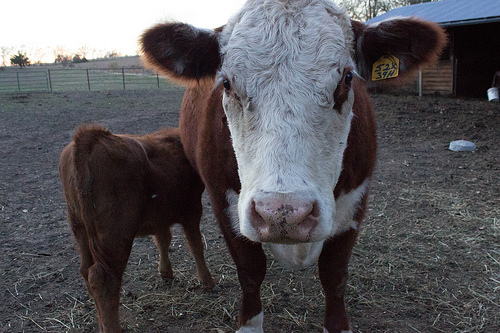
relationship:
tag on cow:
[371, 59, 400, 78] [135, 0, 450, 327]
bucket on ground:
[483, 87, 499, 106] [3, 89, 499, 332]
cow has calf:
[135, 0, 450, 327] [65, 116, 216, 332]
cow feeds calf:
[135, 0, 450, 327] [65, 116, 216, 332]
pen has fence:
[5, 91, 499, 332] [3, 65, 185, 93]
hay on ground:
[2, 90, 499, 332] [3, 89, 499, 332]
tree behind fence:
[13, 53, 27, 67] [3, 65, 185, 93]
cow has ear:
[135, 0, 450, 327] [361, 18, 444, 79]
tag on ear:
[371, 59, 400, 78] [361, 18, 444, 79]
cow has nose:
[135, 0, 450, 327] [248, 188, 323, 240]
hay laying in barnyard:
[0, 91, 500, 332] [0, 0, 500, 333]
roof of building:
[336, 9, 498, 43] [373, 0, 493, 95]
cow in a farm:
[135, 0, 450, 327] [2, 1, 494, 329]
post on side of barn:
[414, 70, 426, 97] [361, 0, 496, 101]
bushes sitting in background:
[56, 52, 66, 64] [2, 3, 246, 70]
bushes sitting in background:
[61, 56, 73, 64] [2, 3, 246, 70]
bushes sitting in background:
[70, 53, 81, 65] [2, 3, 246, 70]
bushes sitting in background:
[81, 55, 89, 62] [2, 3, 246, 70]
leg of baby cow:
[180, 207, 222, 289] [58, 121, 225, 332]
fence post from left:
[83, 67, 90, 88] [0, 3, 12, 327]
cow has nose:
[135, 0, 450, 327] [242, 191, 331, 245]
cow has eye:
[135, 0, 450, 327] [330, 58, 362, 99]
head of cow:
[139, 5, 449, 246] [135, 0, 450, 327]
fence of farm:
[0, 67, 174, 90] [2, 1, 494, 329]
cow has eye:
[135, 0, 450, 327] [216, 76, 235, 99]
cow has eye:
[135, 0, 450, 327] [337, 66, 356, 105]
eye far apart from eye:
[216, 76, 235, 99] [337, 66, 356, 105]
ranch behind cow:
[369, 11, 498, 111] [135, 0, 449, 333]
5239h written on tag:
[375, 58, 396, 75] [371, 56, 402, 80]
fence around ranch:
[2, 68, 173, 92] [2, 4, 496, 331]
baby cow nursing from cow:
[56, 102, 214, 331] [135, 0, 450, 327]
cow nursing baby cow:
[135, 0, 450, 327] [56, 102, 214, 331]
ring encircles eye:
[332, 65, 355, 115] [340, 74, 351, 95]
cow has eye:
[135, 0, 450, 327] [340, 74, 351, 95]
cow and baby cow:
[135, 0, 450, 327] [58, 121, 225, 332]